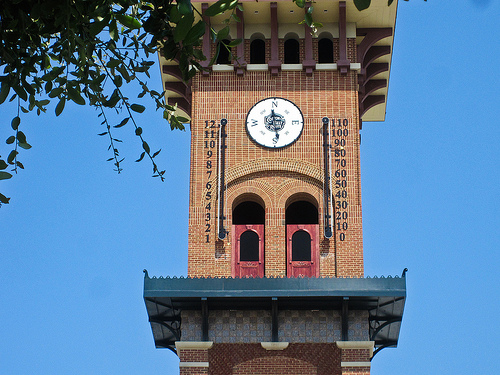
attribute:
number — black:
[328, 118, 348, 208]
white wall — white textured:
[178, 306, 373, 353]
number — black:
[327, 117, 354, 128]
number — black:
[331, 142, 348, 160]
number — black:
[335, 198, 349, 210]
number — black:
[334, 178, 351, 190]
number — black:
[336, 230, 352, 245]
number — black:
[332, 156, 351, 168]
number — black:
[331, 127, 349, 139]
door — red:
[231, 224, 266, 278]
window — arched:
[231, 192, 263, 224]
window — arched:
[286, 191, 318, 225]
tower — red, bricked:
[143, 1, 409, 373]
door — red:
[282, 226, 320, 285]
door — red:
[236, 216, 263, 273]